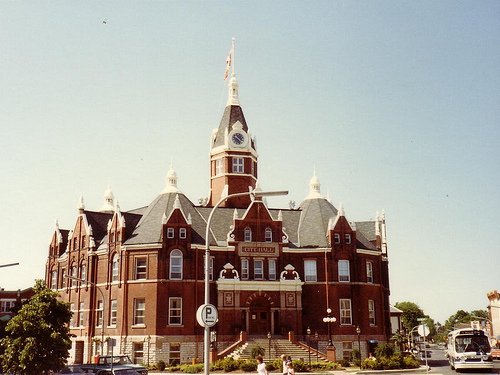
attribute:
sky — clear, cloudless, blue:
[4, 10, 498, 288]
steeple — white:
[206, 31, 259, 154]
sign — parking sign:
[180, 300, 260, 339]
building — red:
[47, 55, 413, 366]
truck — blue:
[42, 316, 164, 373]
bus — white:
[443, 327, 496, 372]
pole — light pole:
[200, 182, 254, 372]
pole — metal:
[202, 195, 229, 369]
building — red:
[61, 47, 388, 371]